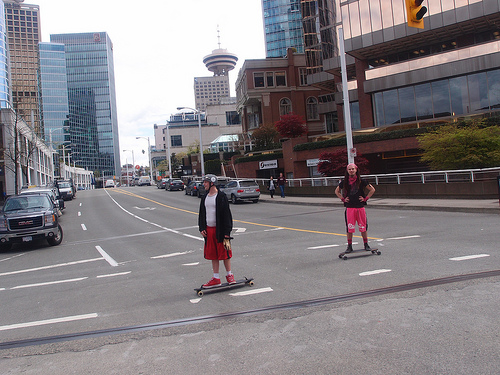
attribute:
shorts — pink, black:
[343, 206, 368, 234]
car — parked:
[0, 188, 67, 251]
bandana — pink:
[344, 162, 354, 167]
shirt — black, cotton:
[318, 179, 389, 216]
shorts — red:
[203, 227, 230, 259]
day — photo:
[10, 5, 498, 373]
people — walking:
[248, 162, 305, 209]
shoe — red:
[227, 272, 234, 281]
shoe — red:
[199, 278, 220, 288]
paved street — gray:
[75, 186, 300, 313]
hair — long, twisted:
[339, 170, 362, 200]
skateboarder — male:
[187, 167, 239, 289]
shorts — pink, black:
[336, 203, 374, 237]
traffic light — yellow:
[401, 1, 426, 29]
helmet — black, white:
[201, 172, 230, 191]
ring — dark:
[196, 54, 239, 61]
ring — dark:
[204, 61, 237, 68]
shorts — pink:
[326, 199, 408, 252]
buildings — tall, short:
[151, 2, 497, 157]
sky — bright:
[31, 2, 281, 169]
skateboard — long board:
[196, 277, 256, 296]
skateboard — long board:
[337, 245, 381, 261]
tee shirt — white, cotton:
[186, 188, 234, 240]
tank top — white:
[202, 192, 219, 226]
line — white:
[90, 240, 123, 277]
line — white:
[77, 217, 92, 234]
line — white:
[75, 204, 85, 219]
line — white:
[77, 200, 83, 208]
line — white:
[103, 181, 208, 256]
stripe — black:
[222, 252, 230, 262]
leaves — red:
[285, 117, 299, 136]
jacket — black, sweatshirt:
[217, 194, 232, 243]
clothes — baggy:
[194, 185, 242, 271]